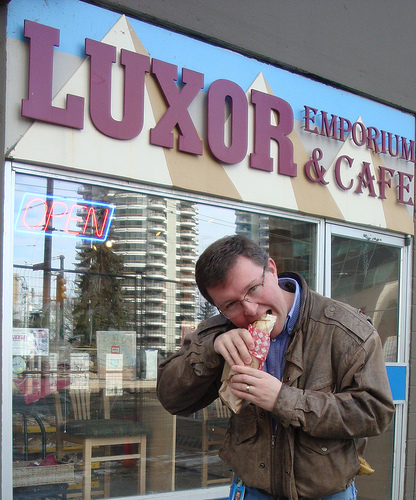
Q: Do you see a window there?
A: Yes, there is a window.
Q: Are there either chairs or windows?
A: Yes, there is a window.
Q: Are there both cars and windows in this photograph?
A: No, there is a window but no cars.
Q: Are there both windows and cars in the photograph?
A: No, there is a window but no cars.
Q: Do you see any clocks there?
A: No, there are no clocks.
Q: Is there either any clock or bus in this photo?
A: No, there are no clocks or buses.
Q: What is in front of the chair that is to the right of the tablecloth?
A: The window is in front of the chair.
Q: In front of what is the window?
A: The window is in front of the chair.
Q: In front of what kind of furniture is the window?
A: The window is in front of the chair.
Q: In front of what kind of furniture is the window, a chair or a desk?
A: The window is in front of a chair.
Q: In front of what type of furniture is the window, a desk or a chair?
A: The window is in front of a chair.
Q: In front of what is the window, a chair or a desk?
A: The window is in front of a chair.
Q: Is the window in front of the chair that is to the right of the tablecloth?
A: Yes, the window is in front of the chair.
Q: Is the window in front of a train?
A: No, the window is in front of the chair.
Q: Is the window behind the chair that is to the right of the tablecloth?
A: No, the window is in front of the chair.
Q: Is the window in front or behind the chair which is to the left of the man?
A: The window is in front of the chair.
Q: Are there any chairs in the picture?
A: Yes, there is a chair.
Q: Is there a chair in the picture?
A: Yes, there is a chair.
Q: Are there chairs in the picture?
A: Yes, there is a chair.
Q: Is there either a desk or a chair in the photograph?
A: Yes, there is a chair.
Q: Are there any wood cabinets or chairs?
A: Yes, there is a wood chair.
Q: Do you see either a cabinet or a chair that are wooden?
A: Yes, the chair is wooden.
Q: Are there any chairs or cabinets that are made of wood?
A: Yes, the chair is made of wood.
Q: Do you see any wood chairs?
A: Yes, there is a wood chair.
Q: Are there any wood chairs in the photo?
A: Yes, there is a wood chair.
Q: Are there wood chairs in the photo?
A: Yes, there is a wood chair.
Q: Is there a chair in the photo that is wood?
A: Yes, there is a wood chair.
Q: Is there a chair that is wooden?
A: Yes, there is a chair that is wooden.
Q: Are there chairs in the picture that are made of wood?
A: Yes, there is a chair that is made of wood.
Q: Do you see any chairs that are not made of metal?
A: Yes, there is a chair that is made of wood.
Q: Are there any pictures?
A: No, there are no pictures.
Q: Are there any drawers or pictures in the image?
A: No, there are no pictures or drawers.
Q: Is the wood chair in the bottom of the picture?
A: Yes, the chair is in the bottom of the image.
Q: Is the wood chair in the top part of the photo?
A: No, the chair is in the bottom of the image.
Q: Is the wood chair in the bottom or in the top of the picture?
A: The chair is in the bottom of the image.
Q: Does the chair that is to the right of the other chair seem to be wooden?
A: Yes, the chair is wooden.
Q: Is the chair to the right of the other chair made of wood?
A: Yes, the chair is made of wood.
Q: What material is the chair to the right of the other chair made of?
A: The chair is made of wood.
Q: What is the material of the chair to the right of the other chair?
A: The chair is made of wood.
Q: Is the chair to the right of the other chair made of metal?
A: No, the chair is made of wood.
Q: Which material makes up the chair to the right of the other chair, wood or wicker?
A: The chair is made of wood.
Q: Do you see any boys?
A: No, there are no boys.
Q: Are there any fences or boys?
A: No, there are no boys or fences.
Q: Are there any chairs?
A: Yes, there is a chair.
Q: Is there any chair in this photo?
A: Yes, there is a chair.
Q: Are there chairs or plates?
A: Yes, there is a chair.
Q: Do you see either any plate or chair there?
A: Yes, there is a chair.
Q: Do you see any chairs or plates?
A: Yes, there is a chair.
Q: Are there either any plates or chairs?
A: Yes, there is a chair.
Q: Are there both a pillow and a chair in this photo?
A: No, there is a chair but no pillows.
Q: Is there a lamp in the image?
A: No, there are no lamps.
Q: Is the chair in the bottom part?
A: Yes, the chair is in the bottom of the image.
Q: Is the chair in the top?
A: No, the chair is in the bottom of the image.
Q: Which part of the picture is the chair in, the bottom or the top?
A: The chair is in the bottom of the image.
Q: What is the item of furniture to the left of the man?
A: The piece of furniture is a chair.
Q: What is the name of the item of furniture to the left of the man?
A: The piece of furniture is a chair.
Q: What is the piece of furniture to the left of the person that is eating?
A: The piece of furniture is a chair.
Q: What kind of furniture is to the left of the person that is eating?
A: The piece of furniture is a chair.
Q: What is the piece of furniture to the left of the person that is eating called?
A: The piece of furniture is a chair.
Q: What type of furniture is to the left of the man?
A: The piece of furniture is a chair.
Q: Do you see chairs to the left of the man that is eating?
A: Yes, there is a chair to the left of the man.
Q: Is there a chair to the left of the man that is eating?
A: Yes, there is a chair to the left of the man.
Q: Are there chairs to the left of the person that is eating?
A: Yes, there is a chair to the left of the man.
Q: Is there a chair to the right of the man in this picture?
A: No, the chair is to the left of the man.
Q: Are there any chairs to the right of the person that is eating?
A: No, the chair is to the left of the man.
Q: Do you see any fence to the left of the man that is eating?
A: No, there is a chair to the left of the man.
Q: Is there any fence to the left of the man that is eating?
A: No, there is a chair to the left of the man.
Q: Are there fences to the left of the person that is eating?
A: No, there is a chair to the left of the man.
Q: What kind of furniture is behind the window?
A: The piece of furniture is a chair.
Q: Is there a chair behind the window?
A: Yes, there is a chair behind the window.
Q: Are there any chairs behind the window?
A: Yes, there is a chair behind the window.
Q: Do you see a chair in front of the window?
A: No, the chair is behind the window.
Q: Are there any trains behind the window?
A: No, there is a chair behind the window.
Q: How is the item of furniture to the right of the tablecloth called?
A: The piece of furniture is a chair.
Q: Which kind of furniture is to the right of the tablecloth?
A: The piece of furniture is a chair.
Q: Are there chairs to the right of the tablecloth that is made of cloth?
A: Yes, there is a chair to the right of the tablecloth.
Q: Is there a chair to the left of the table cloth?
A: No, the chair is to the right of the table cloth.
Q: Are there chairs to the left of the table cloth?
A: No, the chair is to the right of the table cloth.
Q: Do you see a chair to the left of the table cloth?
A: No, the chair is to the right of the table cloth.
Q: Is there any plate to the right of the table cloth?
A: No, there is a chair to the right of the table cloth.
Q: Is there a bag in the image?
A: No, there are no bags.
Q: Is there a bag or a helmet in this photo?
A: No, there are no bags or helmets.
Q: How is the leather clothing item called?
A: The clothing item is a jacket.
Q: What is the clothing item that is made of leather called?
A: The clothing item is a jacket.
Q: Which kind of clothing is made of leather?
A: The clothing is a jacket.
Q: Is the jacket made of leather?
A: Yes, the jacket is made of leather.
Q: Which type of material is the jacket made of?
A: The jacket is made of leather.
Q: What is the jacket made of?
A: The jacket is made of leather.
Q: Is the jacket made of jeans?
A: No, the jacket is made of leather.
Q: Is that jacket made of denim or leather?
A: The jacket is made of leather.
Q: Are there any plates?
A: No, there are no plates.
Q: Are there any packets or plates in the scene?
A: No, there are no plates or packets.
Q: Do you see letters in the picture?
A: Yes, there are letters.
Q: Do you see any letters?
A: Yes, there are letters.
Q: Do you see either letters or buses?
A: Yes, there are letters.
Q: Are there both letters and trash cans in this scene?
A: No, there are letters but no trash cans.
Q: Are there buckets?
A: No, there are no buckets.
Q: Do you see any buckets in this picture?
A: No, there are no buckets.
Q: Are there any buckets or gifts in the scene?
A: No, there are no buckets or gifts.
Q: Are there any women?
A: No, there are no women.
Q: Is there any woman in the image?
A: No, there are no women.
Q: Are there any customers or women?
A: No, there are no women or customers.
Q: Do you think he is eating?
A: Yes, the man is eating.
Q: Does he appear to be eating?
A: Yes, the man is eating.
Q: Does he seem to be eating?
A: Yes, the man is eating.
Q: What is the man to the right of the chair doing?
A: The man is eating.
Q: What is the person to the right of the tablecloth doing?
A: The man is eating.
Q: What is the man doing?
A: The man is eating.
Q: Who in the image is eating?
A: The man is eating.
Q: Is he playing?
A: No, the man is eating.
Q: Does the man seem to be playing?
A: No, the man is eating.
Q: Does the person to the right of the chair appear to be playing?
A: No, the man is eating.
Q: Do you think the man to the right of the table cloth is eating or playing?
A: The man is eating.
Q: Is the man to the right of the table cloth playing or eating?
A: The man is eating.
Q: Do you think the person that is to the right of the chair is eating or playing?
A: The man is eating.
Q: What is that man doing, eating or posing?
A: The man is eating.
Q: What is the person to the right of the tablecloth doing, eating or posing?
A: The man is eating.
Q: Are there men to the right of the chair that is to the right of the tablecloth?
A: Yes, there is a man to the right of the chair.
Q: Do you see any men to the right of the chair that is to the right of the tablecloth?
A: Yes, there is a man to the right of the chair.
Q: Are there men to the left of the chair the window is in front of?
A: No, the man is to the right of the chair.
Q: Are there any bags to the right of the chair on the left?
A: No, there is a man to the right of the chair.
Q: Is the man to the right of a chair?
A: Yes, the man is to the right of a chair.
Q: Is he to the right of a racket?
A: No, the man is to the right of a chair.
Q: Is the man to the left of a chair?
A: No, the man is to the right of a chair.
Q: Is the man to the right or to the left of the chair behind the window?
A: The man is to the right of the chair.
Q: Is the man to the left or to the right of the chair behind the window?
A: The man is to the right of the chair.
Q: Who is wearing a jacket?
A: The man is wearing a jacket.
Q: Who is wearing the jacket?
A: The man is wearing a jacket.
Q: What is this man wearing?
A: The man is wearing a jacket.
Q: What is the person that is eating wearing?
A: The man is wearing a jacket.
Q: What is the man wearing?
A: The man is wearing a jacket.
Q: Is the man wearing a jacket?
A: Yes, the man is wearing a jacket.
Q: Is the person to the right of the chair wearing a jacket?
A: Yes, the man is wearing a jacket.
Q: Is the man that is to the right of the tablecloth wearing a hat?
A: No, the man is wearing a jacket.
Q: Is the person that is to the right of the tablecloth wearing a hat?
A: No, the man is wearing a jacket.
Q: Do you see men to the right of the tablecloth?
A: Yes, there is a man to the right of the tablecloth.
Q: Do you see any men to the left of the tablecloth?
A: No, the man is to the right of the tablecloth.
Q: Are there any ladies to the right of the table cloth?
A: No, there is a man to the right of the table cloth.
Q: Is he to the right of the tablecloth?
A: Yes, the man is to the right of the tablecloth.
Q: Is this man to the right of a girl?
A: No, the man is to the right of the tablecloth.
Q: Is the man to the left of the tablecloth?
A: No, the man is to the right of the tablecloth.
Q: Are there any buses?
A: No, there are no buses.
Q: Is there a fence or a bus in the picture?
A: No, there are no buses or fences.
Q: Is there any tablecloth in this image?
A: Yes, there is a tablecloth.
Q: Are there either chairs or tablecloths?
A: Yes, there is a tablecloth.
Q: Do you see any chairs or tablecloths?
A: Yes, there is a tablecloth.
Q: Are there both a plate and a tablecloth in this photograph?
A: No, there is a tablecloth but no plates.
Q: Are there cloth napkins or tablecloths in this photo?
A: Yes, there is a cloth tablecloth.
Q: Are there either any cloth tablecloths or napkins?
A: Yes, there is a cloth tablecloth.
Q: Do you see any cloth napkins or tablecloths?
A: Yes, there is a cloth tablecloth.